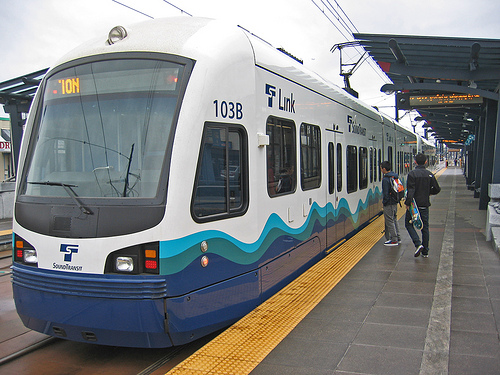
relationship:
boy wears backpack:
[380, 161, 402, 246] [386, 173, 404, 198]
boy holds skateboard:
[403, 153, 441, 257] [402, 189, 423, 231]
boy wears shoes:
[380, 161, 402, 246] [383, 241, 400, 249]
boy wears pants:
[380, 161, 402, 246] [379, 202, 401, 243]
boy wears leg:
[377, 160, 399, 252] [382, 204, 401, 242]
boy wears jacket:
[380, 161, 402, 246] [382, 171, 399, 206]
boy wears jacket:
[403, 149, 441, 262] [403, 166, 441, 207]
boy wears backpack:
[380, 161, 402, 246] [388, 169, 403, 204]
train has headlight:
[9, 16, 439, 348] [21, 248, 133, 271]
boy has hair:
[403, 153, 441, 257] [412, 151, 428, 164]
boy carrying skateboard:
[403, 153, 441, 257] [403, 186, 428, 229]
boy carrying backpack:
[380, 161, 402, 246] [387, 169, 411, 199]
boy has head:
[403, 153, 441, 257] [413, 148, 428, 168]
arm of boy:
[402, 167, 417, 212] [380, 161, 402, 246]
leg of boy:
[379, 202, 399, 237] [403, 153, 441, 257]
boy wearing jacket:
[380, 161, 402, 246] [380, 172, 398, 208]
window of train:
[189, 121, 248, 225] [34, 33, 438, 373]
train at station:
[9, 16, 439, 348] [135, 49, 494, 375]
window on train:
[262, 105, 299, 210] [9, 16, 439, 348]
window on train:
[189, 118, 251, 224] [9, 16, 439, 348]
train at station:
[9, 16, 439, 348] [155, 64, 498, 374]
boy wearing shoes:
[380, 161, 402, 246] [383, 234, 399, 246]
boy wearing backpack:
[380, 161, 402, 246] [386, 170, 408, 198]